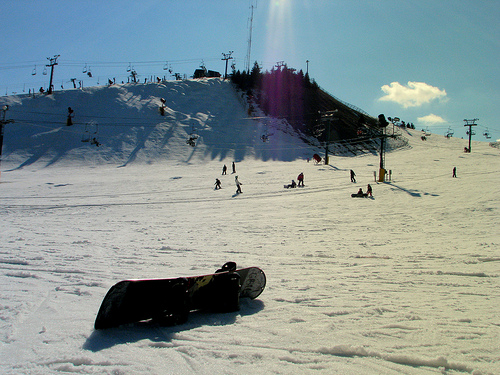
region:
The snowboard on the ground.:
[90, 257, 267, 329]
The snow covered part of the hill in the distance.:
[9, 68, 304, 180]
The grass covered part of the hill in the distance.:
[244, 45, 387, 148]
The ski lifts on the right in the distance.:
[395, 109, 497, 147]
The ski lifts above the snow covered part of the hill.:
[7, 52, 238, 85]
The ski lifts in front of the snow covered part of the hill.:
[9, 93, 321, 160]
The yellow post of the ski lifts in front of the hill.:
[373, 163, 395, 190]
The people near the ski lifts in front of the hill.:
[205, 157, 472, 199]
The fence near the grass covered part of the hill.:
[335, 87, 379, 122]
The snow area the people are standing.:
[13, 151, 498, 363]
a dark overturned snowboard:
[95, 261, 266, 346]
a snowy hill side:
[3, 75, 303, 170]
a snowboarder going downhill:
[210, 175, 222, 190]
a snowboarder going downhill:
[231, 172, 242, 197]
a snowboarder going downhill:
[218, 161, 226, 174]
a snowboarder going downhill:
[228, 157, 234, 172]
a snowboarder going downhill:
[298, 171, 303, 184]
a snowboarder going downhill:
[347, 166, 357, 182]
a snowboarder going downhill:
[158, 101, 165, 116]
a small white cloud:
[371, 79, 449, 111]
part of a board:
[246, 284, 256, 298]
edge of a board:
[166, 277, 178, 279]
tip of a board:
[180, 276, 191, 281]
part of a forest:
[273, 75, 293, 98]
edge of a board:
[150, 289, 170, 299]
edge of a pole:
[381, 155, 388, 178]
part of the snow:
[338, 223, 375, 289]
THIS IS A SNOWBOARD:
[94, 258, 281, 336]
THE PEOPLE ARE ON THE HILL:
[7, 54, 308, 193]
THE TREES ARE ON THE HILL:
[223, 52, 387, 156]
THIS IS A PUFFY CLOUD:
[373, 63, 448, 133]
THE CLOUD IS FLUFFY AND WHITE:
[368, 71, 448, 133]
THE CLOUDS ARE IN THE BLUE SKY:
[1, 0, 499, 148]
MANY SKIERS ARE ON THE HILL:
[4, 79, 373, 184]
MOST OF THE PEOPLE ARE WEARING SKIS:
[8, 68, 459, 215]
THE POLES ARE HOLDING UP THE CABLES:
[2, 38, 494, 207]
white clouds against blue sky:
[295, 14, 372, 50]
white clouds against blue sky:
[377, 52, 442, 113]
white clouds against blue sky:
[411, 13, 479, 41]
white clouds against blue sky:
[19, 2, 139, 36]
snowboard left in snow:
[71, 248, 277, 352]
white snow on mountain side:
[274, 217, 329, 282]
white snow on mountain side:
[319, 300, 419, 346]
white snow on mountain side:
[387, 213, 448, 266]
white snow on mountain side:
[25, 197, 113, 257]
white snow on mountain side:
[117, 195, 174, 260]